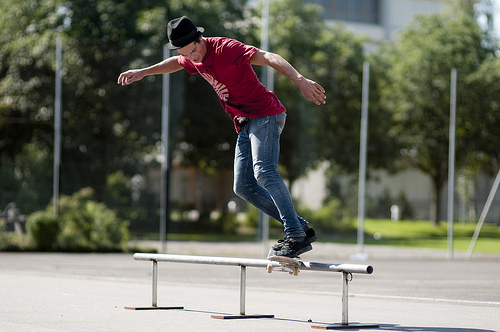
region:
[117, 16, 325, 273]
man performing a trick on a skateboard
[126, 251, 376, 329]
a metal tube on three metal stands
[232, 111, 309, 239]
man wearing blue jeans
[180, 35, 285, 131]
man wearing a red shirt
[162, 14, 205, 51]
man wearing a black hat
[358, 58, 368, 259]
a metal pole in a park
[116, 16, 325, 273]
man keeping his balance on a skateboard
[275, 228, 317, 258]
man wearing black shoes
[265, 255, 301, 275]
a wooden skateboard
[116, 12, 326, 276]
a man standing on a skateboard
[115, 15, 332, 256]
Man wearing black fedora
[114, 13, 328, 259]
Man wearing red shirt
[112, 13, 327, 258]
Man wearing blue jeans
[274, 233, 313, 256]
Black shoe on skateboard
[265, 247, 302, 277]
Skateboard on top of ramp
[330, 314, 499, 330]
Shadow of man on ground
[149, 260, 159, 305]
Pole supporting big pole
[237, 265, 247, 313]
Pole supporting big pole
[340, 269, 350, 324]
Pole supporting big pole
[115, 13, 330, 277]
young male on skateboard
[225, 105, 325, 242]
men's blue denim jeans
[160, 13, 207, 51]
men's black fedora style hat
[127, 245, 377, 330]
low white metal rail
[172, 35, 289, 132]
men's red tee shirt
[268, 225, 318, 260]
men's black athletic footwear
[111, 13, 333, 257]
young man with outstretched arms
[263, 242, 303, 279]
skate board balancing on metal rail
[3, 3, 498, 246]
row of trees behind skate boarder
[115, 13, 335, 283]
man balancing skateboard on rail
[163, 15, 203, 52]
Black hat on top of man's head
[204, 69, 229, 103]
White design on man's red shirt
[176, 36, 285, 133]
Men's short sleeved red shirt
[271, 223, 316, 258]
Black shoes on man's feet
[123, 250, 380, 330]
Metal pole on supports attached to concrete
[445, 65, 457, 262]
Metal pole in the background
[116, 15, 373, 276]
Man in red shirt riding skateboard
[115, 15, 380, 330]
Man riding skateboard on top of metal pole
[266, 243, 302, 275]
Skateboard sitting on top of pole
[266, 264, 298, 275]
Wheels under the skateboard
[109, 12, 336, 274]
man balancing board on rail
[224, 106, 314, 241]
man's blue denim pants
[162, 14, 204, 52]
men's black fedora hat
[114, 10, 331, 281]
man with outstretched arms on skateboard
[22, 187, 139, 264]
low bush in background on left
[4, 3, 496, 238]
row of tees behind boarder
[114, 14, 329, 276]
man leaning to maintain balance